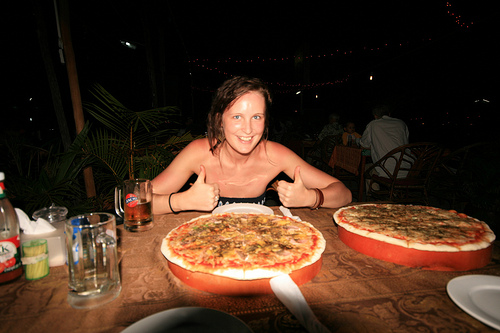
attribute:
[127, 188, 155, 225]
glass — empty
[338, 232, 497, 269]
pizza tray — red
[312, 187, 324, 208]
wristbands — brown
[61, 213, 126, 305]
mug — empty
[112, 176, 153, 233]
glass mug — clear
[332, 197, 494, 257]
pizza — large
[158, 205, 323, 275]
pizza — large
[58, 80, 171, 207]
plants — tropical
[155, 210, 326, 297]
pizza — large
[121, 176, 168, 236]
mug — glass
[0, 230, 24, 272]
label — red, white, green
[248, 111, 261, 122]
eye — blue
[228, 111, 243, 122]
eye — blue